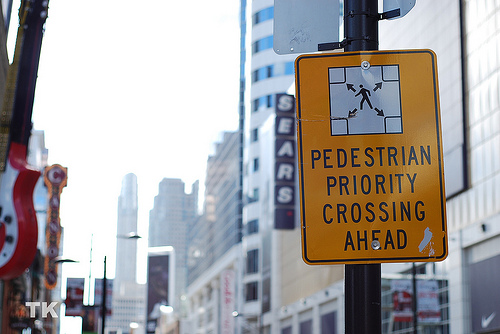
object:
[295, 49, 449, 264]
sign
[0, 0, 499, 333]
cityscape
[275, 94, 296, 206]
sears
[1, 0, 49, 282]
guitar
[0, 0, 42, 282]
sign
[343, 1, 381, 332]
pole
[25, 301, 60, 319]
logo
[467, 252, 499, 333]
sign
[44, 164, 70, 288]
sign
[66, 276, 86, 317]
flag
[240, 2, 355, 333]
building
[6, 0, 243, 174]
sky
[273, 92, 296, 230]
sign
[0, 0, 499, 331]
photo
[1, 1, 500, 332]
day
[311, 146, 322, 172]
words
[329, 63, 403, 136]
square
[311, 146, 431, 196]
pedestrian priority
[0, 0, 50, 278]
out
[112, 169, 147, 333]
buildings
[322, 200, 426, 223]
crossing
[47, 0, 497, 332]
background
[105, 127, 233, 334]
distance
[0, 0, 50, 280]
left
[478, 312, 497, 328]
logo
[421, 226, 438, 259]
scratch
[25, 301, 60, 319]
tk letters